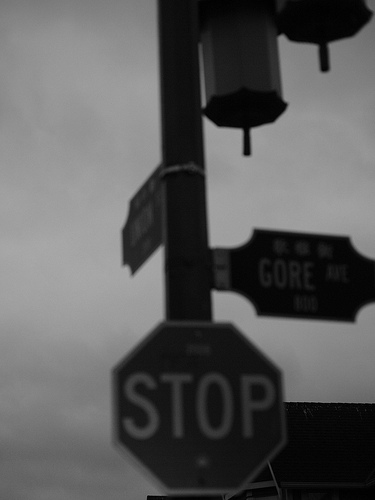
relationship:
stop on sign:
[127, 371, 274, 447] [105, 318, 293, 496]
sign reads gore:
[229, 220, 374, 324] [256, 253, 316, 296]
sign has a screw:
[105, 318, 293, 496] [193, 331, 206, 339]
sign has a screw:
[105, 318, 293, 496] [194, 455, 208, 470]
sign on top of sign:
[105, 318, 293, 496] [229, 220, 374, 324]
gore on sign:
[256, 253, 316, 296] [229, 220, 374, 324]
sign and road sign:
[105, 318, 293, 496] [117, 171, 167, 270]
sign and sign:
[105, 318, 293, 496] [229, 220, 374, 324]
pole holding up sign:
[157, 3, 213, 323] [105, 318, 293, 496]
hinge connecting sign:
[210, 249, 233, 292] [229, 220, 374, 324]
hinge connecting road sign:
[160, 164, 204, 183] [117, 171, 167, 270]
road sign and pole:
[117, 171, 167, 270] [157, 3, 213, 323]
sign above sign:
[229, 220, 374, 324] [105, 318, 293, 496]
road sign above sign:
[117, 171, 167, 270] [105, 318, 293, 496]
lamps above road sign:
[192, 2, 371, 156] [117, 171, 167, 270]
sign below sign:
[105, 318, 293, 496] [229, 220, 374, 324]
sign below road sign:
[105, 318, 293, 496] [117, 171, 167, 270]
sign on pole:
[105, 318, 293, 496] [157, 3, 213, 323]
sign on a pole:
[105, 318, 293, 496] [157, 3, 213, 323]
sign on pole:
[229, 220, 374, 324] [157, 3, 213, 323]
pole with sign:
[157, 3, 213, 323] [105, 318, 293, 496]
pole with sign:
[157, 3, 213, 323] [229, 220, 374, 324]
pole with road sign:
[157, 3, 213, 323] [117, 171, 167, 270]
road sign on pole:
[117, 171, 167, 270] [157, 3, 213, 323]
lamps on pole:
[192, 2, 371, 156] [157, 3, 213, 323]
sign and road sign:
[229, 220, 374, 324] [117, 171, 167, 270]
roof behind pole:
[270, 392, 374, 486] [157, 3, 213, 323]